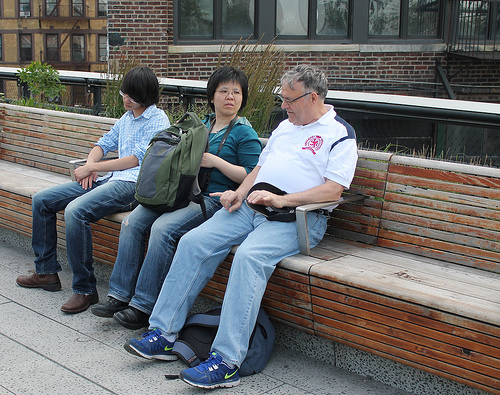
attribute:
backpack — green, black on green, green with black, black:
[137, 112, 217, 212]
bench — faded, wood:
[3, 106, 500, 391]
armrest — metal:
[69, 160, 91, 178]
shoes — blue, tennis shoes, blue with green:
[124, 328, 240, 390]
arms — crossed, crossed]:
[71, 128, 141, 186]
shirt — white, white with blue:
[259, 107, 360, 213]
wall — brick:
[111, 0, 500, 88]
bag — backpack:
[174, 302, 277, 371]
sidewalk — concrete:
[1, 223, 500, 392]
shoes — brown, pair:
[12, 271, 100, 315]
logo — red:
[306, 135, 323, 160]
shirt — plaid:
[96, 102, 171, 182]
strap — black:
[202, 115, 238, 156]